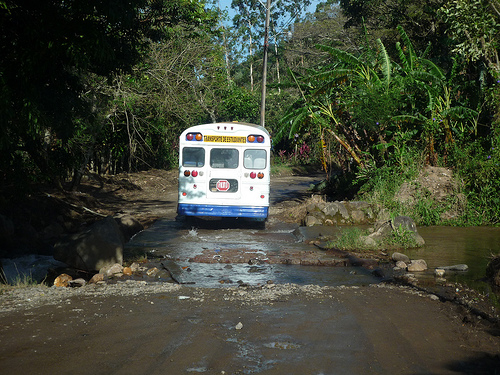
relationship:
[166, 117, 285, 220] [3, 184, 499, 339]
bus in water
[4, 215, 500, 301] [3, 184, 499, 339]
stones in water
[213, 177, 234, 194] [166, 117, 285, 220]
sign on bus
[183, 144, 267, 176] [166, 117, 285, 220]
windows on bus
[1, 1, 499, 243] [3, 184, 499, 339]
trees surrounding water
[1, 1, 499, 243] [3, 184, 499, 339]
trees near water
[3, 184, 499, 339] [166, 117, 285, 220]
water near bus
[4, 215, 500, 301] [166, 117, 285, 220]
stones near bus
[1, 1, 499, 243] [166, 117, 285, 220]
trees near bus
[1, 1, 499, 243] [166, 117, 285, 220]
trees around bus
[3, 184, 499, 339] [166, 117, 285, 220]
water under bus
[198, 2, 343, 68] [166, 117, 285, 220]
sky above bus